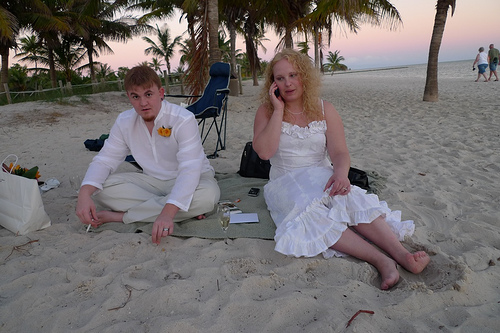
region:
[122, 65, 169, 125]
the head of a man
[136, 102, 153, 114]
the mouth of a man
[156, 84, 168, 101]
the ear of a man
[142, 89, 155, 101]
the eye of a man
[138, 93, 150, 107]
the nose of a man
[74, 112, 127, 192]
the arm of a man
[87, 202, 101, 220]
the thumb of a man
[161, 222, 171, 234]
a ring on the finger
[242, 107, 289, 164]
the arm of a woman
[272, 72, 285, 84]
the eye of a woman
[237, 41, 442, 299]
Woman is sitting on beach.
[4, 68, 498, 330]
The beach is sandy.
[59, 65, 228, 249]
The man is holding a cigarette.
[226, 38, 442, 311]
The woman is barefoot.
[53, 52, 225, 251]
Ther man is barefoot.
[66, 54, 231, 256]
The man is wearing a wedding band.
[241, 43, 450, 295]
Woman wearing a ring on her left hand.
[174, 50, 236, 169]
The chair is blue.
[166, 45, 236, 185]
The chair is portable.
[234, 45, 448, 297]
The woman has blonde hair.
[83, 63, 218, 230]
Man wearing a white shirt.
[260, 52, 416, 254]
Woman wearing white summer dress.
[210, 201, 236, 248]
Champagne flute sitting on sand.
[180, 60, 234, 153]
Dark colored chair.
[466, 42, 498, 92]
Couple walking on beach.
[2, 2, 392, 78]
Palm trees on beach.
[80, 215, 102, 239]
Man has a cigarette.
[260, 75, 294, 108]
Woman is holding a phone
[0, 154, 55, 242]
Beige shopping bag.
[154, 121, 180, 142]
Small orange flowers on mans' shirt.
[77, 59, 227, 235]
A man in dressed in white sitting on the sand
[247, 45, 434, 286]
a woman dressed in white sitting in the sand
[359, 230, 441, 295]
Bare feet on the sand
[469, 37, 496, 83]
A man and a woman walking on the sand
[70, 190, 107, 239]
a hand holding a cigarette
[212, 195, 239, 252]
a glass sitting on the sand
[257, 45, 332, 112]
a woman talking on a cell phone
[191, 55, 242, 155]
an opened blue beach chair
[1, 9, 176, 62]
green palm trees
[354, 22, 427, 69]
a beautiful red and blue horizon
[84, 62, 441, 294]
BRIDE AND GROOM AFTER THE WEDDING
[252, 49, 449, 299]
WOMAN IS WEARING NO SHOES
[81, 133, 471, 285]
PEOPLE ARE SITTING ON A BLANKET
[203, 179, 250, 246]
A GLASS OF CHAMPAGNE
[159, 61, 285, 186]
A BLUE CHAIR ON THE SAND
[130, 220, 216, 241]
MAN IS WEARING A RING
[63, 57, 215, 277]
MAN HAS YELLOW CORSAIGE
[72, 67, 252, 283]
MAN IS HOLDING A CIGARETTE IN HIS HAND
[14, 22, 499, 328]
SAND IS ON THE GROUND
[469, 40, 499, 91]
TWO PEOPLE ARE WALKING ON THE BEACH